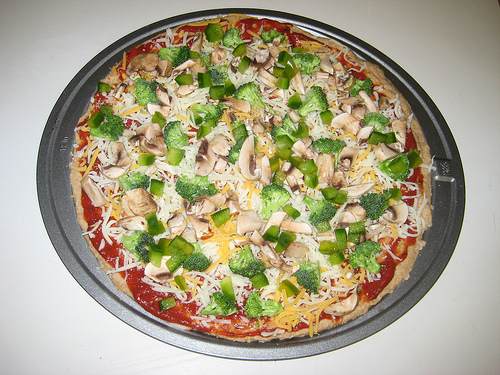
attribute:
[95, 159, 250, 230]
mushroom — piece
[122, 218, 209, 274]
vegatable — green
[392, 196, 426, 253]
cheese — shredded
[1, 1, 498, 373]
table top — white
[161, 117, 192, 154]
vegetable — green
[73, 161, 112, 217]
mushroom — piece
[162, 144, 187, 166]
pepper — green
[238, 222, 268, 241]
mushroom — piece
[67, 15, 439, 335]
pizza — not cooked, uncooked, veggie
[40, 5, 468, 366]
pan — metal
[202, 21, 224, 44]
vegetable — green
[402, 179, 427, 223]
cheese — white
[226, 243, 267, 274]
broccoli floret — small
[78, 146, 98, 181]
cheese — yellow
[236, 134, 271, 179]
mushroom — tan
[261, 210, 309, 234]
mushroom — tan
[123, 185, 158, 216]
mushroom — tan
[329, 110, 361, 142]
mushroom — tan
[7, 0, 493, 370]
platter/table — gray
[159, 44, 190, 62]
broccoli — green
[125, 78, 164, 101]
broccoli — green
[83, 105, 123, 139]
broccoli — green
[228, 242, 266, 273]
broccoli — green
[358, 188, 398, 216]
broccoli — green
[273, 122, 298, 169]
bell pepper — green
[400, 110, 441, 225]
crust — thin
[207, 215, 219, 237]
cheese — cheddar, shredded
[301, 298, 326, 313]
cheese — cheddar, shredded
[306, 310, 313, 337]
cheese — cheddar, shredded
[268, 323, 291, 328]
cheese — cheddar, shredded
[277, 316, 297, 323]
cheese — cheddar, shredded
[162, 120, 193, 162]
vegetable — green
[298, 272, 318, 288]
vegetable — green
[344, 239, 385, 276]
vegetable — green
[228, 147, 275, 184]
mushroom — raw 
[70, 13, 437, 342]
cheese — white, yellow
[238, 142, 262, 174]
mushroom — piece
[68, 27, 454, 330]
sauce — red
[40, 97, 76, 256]
tray — metal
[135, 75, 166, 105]
vegetable — green